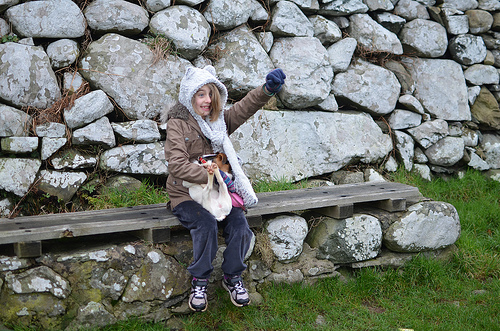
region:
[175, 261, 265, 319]
pair of purple shoes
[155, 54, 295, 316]
young girl on a wooden bench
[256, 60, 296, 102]
hand with blue knit glove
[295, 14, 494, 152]
rock wall with debris between rocks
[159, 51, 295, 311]
young girl holdinn an animal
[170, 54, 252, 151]
young girl with blond hair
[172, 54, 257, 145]
hat with animal ears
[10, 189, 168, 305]
bench on rock wall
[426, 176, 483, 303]
rock and green grass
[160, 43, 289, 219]
girl in brown coat waving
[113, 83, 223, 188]
the rocks are grey and white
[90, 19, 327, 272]
the rocks are grey and white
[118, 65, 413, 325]
the rocks are grey and white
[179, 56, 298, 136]
girl wearing a blue glove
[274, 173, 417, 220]
wooden bench on top rocks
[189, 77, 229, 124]
young girl grinning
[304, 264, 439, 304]
green grass at base of rock bench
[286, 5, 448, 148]
wall of rocks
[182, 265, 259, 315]
tennis shoes with white laces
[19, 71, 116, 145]
dead grass in between the rocks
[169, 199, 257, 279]
girl wearing blue pants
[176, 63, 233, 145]
girl white hoodie with scarf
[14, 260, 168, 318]
rocks with algae growing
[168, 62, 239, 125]
a young girl wearing a white hooded scarf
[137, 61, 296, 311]
a young girl sitting on a bench with a stone wall behind her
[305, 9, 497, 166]
a wall made of stone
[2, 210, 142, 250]
a wooden bench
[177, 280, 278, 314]
blue and white sneakers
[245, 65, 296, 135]
a person raising their hand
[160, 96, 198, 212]
The sleeve of a brown jacket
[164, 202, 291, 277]
person wearing blue suede pants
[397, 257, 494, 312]
Blades of grass on the ground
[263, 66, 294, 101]
a blue glove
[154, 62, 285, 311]
Small child sitting.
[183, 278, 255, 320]
Child has tennis shoes on.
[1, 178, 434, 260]
Top of bench made of wood.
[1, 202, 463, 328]
Bottom of bench made of rocks.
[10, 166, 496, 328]
Grass on the ground.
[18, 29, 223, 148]
Dead grass sticking out of rocks.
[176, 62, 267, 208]
Girl has had on with ears.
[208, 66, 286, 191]
Girl wearing gloves on her hands.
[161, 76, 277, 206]
Girl wearing a coat.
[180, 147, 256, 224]
Girl holding on to items in her lap.